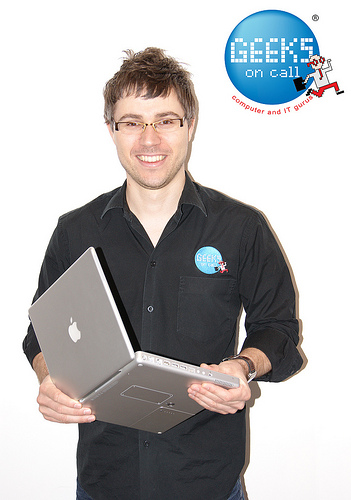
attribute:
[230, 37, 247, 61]
letter — white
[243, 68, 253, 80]
letter — white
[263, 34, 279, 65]
letter — white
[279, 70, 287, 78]
letter — white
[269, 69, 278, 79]
letter — white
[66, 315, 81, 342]
logo — WHITE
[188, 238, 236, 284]
sticker — blue, white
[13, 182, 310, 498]
shirt — black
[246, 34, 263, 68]
letter — white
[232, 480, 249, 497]
pants — blue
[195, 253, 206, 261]
letter — white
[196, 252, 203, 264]
letter — white